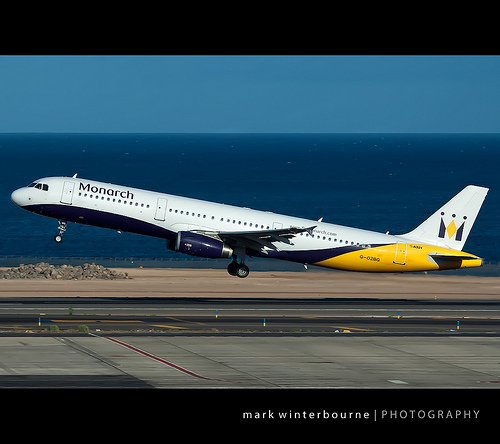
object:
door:
[394, 239, 409, 265]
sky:
[0, 57, 497, 132]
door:
[57, 179, 80, 209]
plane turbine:
[173, 231, 181, 251]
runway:
[1, 334, 500, 390]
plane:
[11, 171, 489, 276]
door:
[155, 195, 166, 224]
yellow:
[386, 248, 407, 265]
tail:
[398, 185, 492, 270]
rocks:
[47, 268, 59, 276]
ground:
[1, 262, 498, 387]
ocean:
[1, 133, 500, 262]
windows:
[78, 191, 82, 195]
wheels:
[235, 264, 251, 278]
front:
[10, 173, 61, 219]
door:
[60, 182, 75, 207]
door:
[272, 223, 282, 235]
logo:
[79, 182, 135, 199]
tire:
[54, 233, 64, 243]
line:
[99, 334, 210, 381]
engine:
[170, 231, 233, 257]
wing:
[192, 218, 318, 250]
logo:
[438, 211, 466, 242]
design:
[264, 244, 483, 272]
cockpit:
[41, 183, 49, 192]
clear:
[0, 54, 499, 134]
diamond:
[446, 218, 458, 239]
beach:
[1, 259, 500, 303]